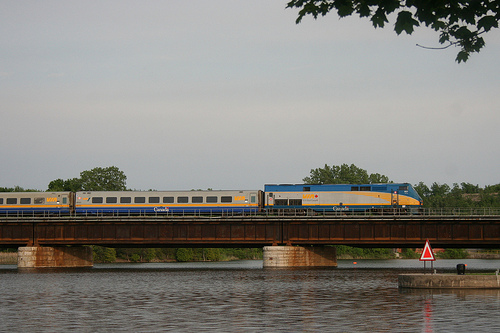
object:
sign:
[420, 241, 437, 275]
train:
[3, 181, 429, 211]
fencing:
[1, 208, 499, 220]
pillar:
[263, 242, 338, 271]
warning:
[419, 237, 434, 260]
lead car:
[267, 183, 425, 208]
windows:
[91, 196, 105, 203]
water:
[0, 257, 498, 331]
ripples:
[0, 265, 498, 332]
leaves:
[391, 10, 420, 36]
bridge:
[0, 220, 499, 269]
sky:
[0, 0, 499, 192]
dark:
[0, 0, 499, 189]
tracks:
[2, 214, 497, 228]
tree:
[281, 0, 499, 63]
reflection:
[422, 291, 438, 329]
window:
[398, 183, 411, 193]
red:
[427, 248, 430, 254]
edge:
[4, 216, 494, 224]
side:
[9, 192, 408, 202]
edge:
[3, 185, 415, 194]